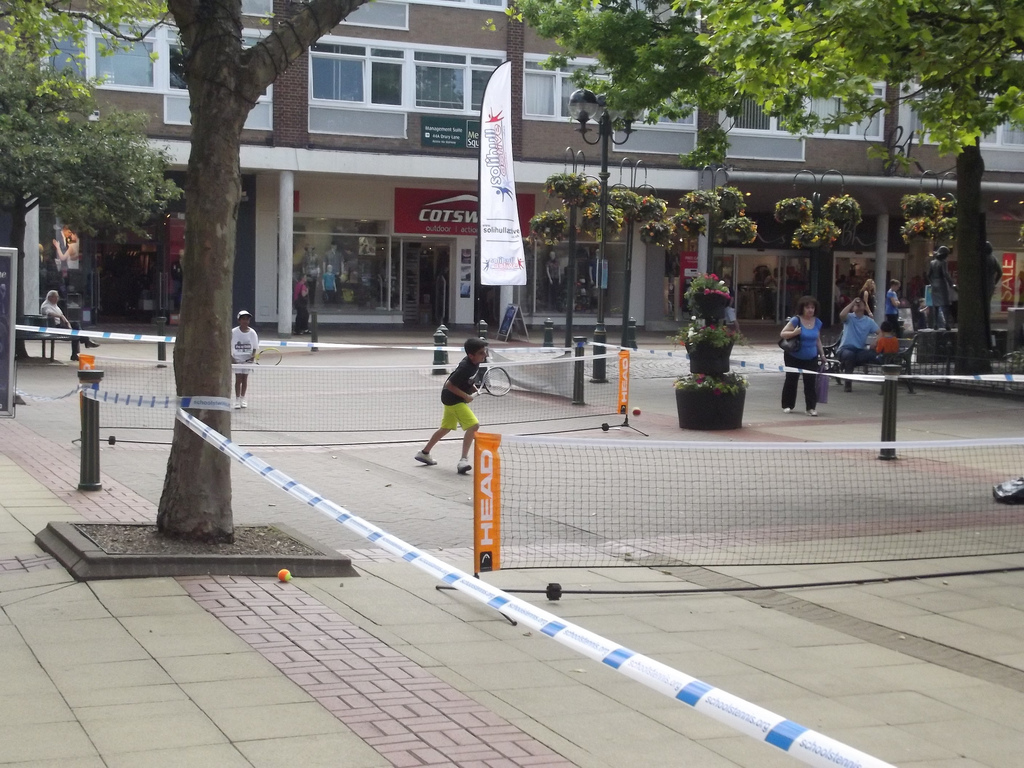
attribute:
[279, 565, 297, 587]
ball — orange, yellow, green, pink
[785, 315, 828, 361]
shirt — blue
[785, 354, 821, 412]
pants — black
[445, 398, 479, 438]
shorts — yellow, green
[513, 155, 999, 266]
flowers — hanging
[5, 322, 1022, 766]
tape — white, blue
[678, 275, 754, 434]
plants — two-tiered, stacked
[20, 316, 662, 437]
net — orange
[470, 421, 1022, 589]
net — orange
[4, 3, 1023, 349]
shop — storefront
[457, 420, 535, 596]
end — orange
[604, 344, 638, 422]
end — orange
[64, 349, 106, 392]
end — orange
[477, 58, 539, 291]
banner — white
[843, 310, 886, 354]
shirt — blue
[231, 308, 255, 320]
cap — white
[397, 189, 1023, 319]
sign — red, white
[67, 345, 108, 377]
border — orange